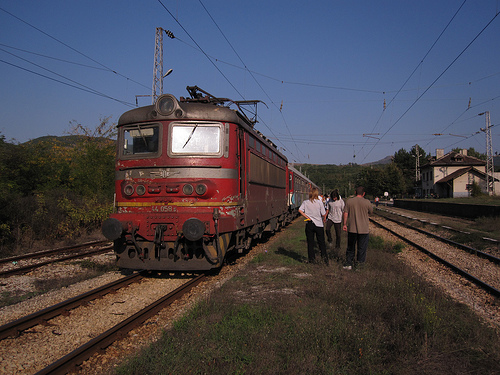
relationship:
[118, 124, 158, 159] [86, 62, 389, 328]
window in train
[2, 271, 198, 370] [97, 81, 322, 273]
tracks in front of train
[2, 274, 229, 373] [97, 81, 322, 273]
gravel in front of train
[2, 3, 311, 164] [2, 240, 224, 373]
wires overhead above tracks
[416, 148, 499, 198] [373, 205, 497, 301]
building by tracks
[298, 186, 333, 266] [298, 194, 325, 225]
person reaching under shirt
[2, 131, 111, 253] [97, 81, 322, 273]
hill on side of train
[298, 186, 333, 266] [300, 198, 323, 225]
person in shirt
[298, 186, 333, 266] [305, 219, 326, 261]
person in pants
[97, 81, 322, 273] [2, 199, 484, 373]
train sitting in field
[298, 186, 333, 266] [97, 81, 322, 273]
person standing next to train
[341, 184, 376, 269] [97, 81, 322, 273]
man standing next to train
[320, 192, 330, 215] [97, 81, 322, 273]
person standing next to train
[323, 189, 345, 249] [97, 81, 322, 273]
person standing next to train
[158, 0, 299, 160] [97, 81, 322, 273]
wire running above train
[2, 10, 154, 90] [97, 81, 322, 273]
wire running above train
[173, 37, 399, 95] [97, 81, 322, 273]
wire running above train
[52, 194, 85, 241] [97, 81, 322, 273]
plant growing near train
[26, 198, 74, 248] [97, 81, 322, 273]
plant growing near train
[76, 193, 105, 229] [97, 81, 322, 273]
plant growing near train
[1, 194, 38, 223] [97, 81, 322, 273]
plant growing near train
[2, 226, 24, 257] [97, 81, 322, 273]
plant growing near train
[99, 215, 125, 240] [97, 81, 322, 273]
bumper mounted on train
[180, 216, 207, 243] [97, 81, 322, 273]
bumper mounted on train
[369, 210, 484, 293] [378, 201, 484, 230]
rail running alongside road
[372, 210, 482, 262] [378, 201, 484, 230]
rail running alongside road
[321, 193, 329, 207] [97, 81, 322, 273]
person standing next to train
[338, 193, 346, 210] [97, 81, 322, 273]
person standing next to train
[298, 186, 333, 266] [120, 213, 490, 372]
person standing in grass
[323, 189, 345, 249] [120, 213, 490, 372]
person standing in grass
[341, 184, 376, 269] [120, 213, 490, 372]
man standing in grass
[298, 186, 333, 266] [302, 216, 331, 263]
person wearing pants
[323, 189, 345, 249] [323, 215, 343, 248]
person wearing pants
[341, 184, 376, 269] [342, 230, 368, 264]
man wearing pants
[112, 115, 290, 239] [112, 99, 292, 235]
surface covering train engine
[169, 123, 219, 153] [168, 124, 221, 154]
light reflecting off windshield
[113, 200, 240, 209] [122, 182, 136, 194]
stripe painted under light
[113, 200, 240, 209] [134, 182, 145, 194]
stripe painted under light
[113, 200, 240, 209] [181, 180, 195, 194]
stripe painted under light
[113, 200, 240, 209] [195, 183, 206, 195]
stripe painted under light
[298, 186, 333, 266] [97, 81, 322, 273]
person stand next to train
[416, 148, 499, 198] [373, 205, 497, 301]
building next to tracks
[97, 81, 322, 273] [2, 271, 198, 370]
train under tracks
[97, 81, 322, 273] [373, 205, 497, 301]
train near tracks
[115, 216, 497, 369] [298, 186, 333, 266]
grass patch under person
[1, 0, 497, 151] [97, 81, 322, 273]
wires above train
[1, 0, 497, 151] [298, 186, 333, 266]
wires above person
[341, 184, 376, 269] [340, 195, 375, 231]
man wearing shirt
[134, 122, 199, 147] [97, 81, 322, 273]
windshield wipers on front train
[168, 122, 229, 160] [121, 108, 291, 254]
window on train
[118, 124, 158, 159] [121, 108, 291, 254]
window on train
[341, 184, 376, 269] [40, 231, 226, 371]
man walking near rails